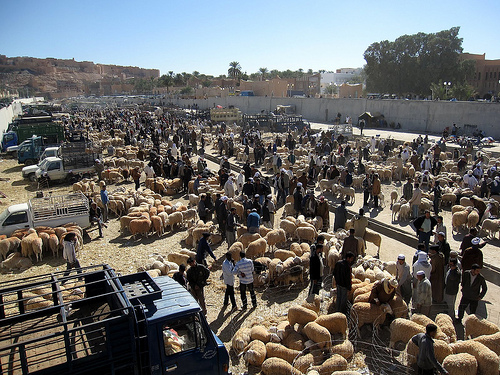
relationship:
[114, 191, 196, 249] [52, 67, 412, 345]
sheep in market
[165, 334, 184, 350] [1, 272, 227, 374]
clothes in truck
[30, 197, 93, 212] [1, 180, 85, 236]
cage on truck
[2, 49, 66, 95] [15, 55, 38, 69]
mountain of rocks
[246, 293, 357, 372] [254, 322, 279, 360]
herd of sheep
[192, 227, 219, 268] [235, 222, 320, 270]
man by herd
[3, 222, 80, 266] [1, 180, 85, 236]
sheep by truck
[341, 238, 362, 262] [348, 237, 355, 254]
man in brown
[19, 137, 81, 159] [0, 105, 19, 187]
truck by fence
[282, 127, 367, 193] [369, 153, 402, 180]
people with sheep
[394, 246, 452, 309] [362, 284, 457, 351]
men watching sheep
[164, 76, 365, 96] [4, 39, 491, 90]
houses in distance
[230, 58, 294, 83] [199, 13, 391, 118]
trees in background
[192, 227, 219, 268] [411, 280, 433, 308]
man wearing shirt